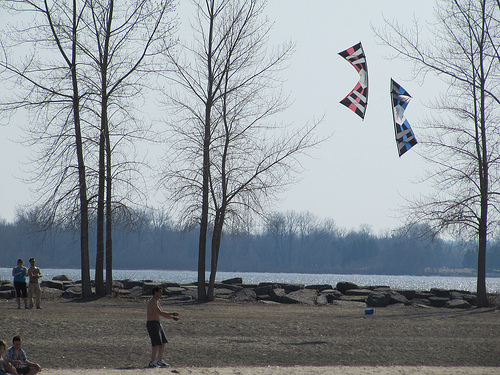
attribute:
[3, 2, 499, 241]
sky — pale, blue, hazy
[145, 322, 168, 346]
shorts — dark colored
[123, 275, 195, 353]
man — shirtless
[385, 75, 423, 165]
kite — blue black and grey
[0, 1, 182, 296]
tree — tall, leafless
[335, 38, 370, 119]
kite — red black and grey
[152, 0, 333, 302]
tree — tall, leafless